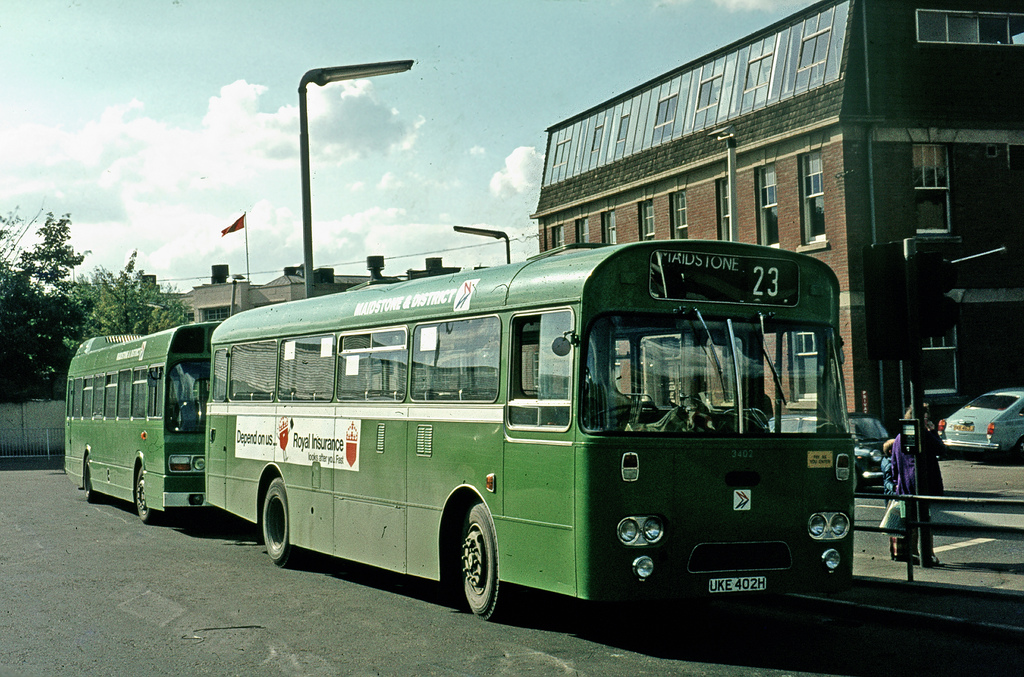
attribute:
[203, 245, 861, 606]
bus — green, parked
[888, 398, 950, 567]
person — standing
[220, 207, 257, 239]
flag — flying, waving, red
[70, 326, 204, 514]
city bus — green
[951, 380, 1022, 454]
car — parked, blue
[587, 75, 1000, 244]
building — brick, large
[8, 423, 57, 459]
barricade — metal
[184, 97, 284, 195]
clouds — white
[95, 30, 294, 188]
sky — blue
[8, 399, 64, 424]
fence — white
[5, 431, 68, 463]
fence — metal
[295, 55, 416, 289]
street lamp — black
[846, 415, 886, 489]
car — driving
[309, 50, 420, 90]
light — tall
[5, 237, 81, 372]
tree — leafy